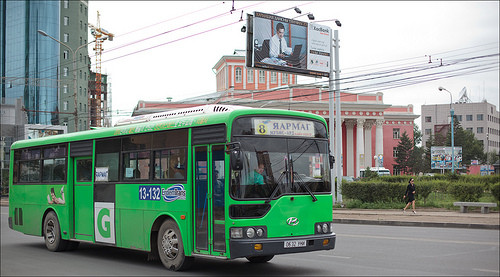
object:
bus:
[4, 101, 344, 272]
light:
[34, 25, 82, 131]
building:
[126, 46, 424, 185]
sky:
[81, 0, 496, 105]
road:
[1, 197, 500, 277]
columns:
[352, 118, 367, 180]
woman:
[401, 173, 423, 215]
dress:
[403, 182, 419, 205]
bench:
[447, 199, 498, 215]